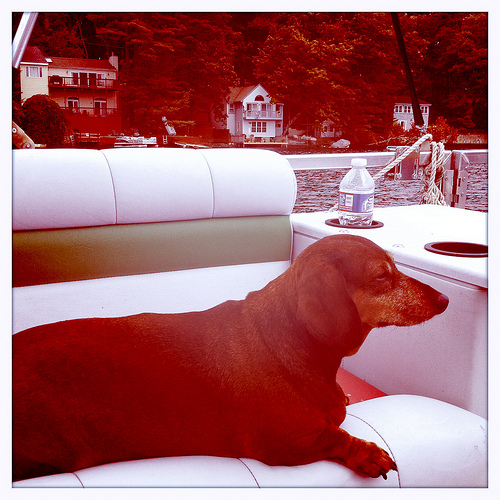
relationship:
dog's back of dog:
[13, 280, 284, 383] [13, 234, 449, 479]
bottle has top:
[336, 157, 377, 229] [348, 157, 369, 167]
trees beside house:
[248, 26, 412, 142] [222, 81, 289, 142]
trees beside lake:
[248, 26, 412, 142] [279, 146, 489, 209]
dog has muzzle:
[13, 234, 449, 479] [360, 274, 449, 328]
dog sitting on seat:
[13, 234, 449, 479] [13, 144, 488, 489]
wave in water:
[301, 172, 334, 204] [295, 167, 493, 207]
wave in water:
[301, 172, 332, 203] [290, 160, 490, 215]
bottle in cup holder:
[320, 161, 394, 223] [322, 215, 383, 231]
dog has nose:
[13, 234, 449, 479] [434, 292, 449, 312]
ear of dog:
[298, 272, 365, 358] [13, 234, 449, 479]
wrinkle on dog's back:
[243, 299, 304, 381] [13, 291, 264, 383]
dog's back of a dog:
[13, 280, 284, 383] [20, 246, 445, 465]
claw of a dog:
[373, 469, 389, 479] [13, 234, 449, 479]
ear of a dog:
[298, 272, 365, 351] [255, 212, 465, 390]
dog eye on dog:
[375, 270, 392, 290] [13, 234, 449, 479]